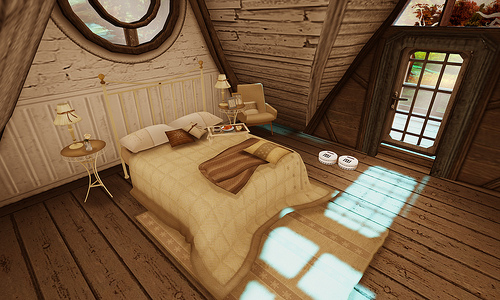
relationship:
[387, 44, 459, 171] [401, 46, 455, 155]
door with panes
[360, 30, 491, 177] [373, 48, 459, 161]
door with windows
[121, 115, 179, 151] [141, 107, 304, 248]
pillow on a bed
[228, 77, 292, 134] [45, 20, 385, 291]
chair in a room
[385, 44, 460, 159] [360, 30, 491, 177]
windows on a door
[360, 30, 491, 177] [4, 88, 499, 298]
door in a room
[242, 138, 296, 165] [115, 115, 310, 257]
pillow on a bed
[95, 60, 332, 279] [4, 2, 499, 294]
bed in room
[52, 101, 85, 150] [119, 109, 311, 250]
lamp next to bed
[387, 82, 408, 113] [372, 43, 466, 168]
handle on door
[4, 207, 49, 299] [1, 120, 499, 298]
line on ground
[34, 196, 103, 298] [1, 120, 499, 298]
line on ground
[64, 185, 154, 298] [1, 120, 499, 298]
line on ground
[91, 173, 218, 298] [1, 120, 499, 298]
line on ground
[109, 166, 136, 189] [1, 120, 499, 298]
line on ground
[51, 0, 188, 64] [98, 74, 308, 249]
round shape above bed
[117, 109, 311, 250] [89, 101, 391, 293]
bed in middle of room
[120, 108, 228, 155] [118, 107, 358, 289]
pillows are in cot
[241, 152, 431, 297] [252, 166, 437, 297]
sunlight reflection on floor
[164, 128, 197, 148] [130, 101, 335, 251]
pillow on bed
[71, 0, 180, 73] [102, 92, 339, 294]
window above bed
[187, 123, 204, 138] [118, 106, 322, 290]
pillow at top of bed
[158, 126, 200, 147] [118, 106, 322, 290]
pillow at top of bed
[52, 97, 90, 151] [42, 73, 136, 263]
lamp on end table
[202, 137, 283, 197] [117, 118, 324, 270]
blanket on top of bed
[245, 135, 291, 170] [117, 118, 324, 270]
pillow on top of bed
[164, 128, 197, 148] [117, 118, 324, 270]
pillow on top of bed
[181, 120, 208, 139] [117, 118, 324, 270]
pillow on top of bed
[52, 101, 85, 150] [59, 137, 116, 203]
lamp on end table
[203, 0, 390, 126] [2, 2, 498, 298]
wall in bedroom